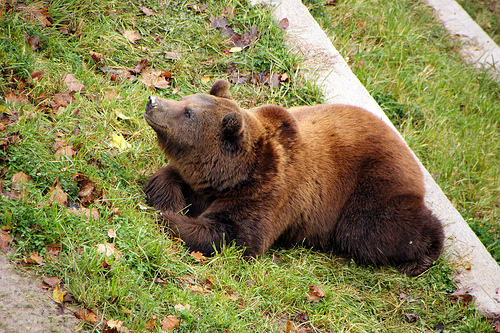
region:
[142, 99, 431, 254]
bear is brown in color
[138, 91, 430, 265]
brown bear is laying on grass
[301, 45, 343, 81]
this is a concrete step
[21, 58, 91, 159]
the grass is green in color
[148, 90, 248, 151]
bear is looking upwards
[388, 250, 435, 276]
this is a bears back paw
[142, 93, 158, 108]
bears nose is black in color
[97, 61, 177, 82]
fallen leaves lying on top of grass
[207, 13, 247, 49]
dead leaves are brown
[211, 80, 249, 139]
brown bear has ears perked up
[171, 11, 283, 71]
leaves in the grass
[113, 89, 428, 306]
bear on the grass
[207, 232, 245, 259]
blades of the grass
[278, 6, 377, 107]
barrier in the grass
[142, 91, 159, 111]
nose of the bear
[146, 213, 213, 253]
paw in the grass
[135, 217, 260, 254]
paw of the bear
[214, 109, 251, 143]
ear of the bear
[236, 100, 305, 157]
scruff of the bears neck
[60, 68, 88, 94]
leaf in the grass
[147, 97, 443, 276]
A brown bear on grass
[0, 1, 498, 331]
Brown leaves spread on grass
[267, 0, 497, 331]
Two white marked areas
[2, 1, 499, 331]
The grass filled space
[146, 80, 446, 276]
The bear with raised ears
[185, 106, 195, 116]
An open bear eye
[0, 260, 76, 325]
The grass free space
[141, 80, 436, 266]
The bear lying on grass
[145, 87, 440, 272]
The bear with a raised head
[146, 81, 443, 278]
A bear with its behind on white surface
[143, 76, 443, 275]
A grizzly bear laying down.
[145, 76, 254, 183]
A grizzly bears head.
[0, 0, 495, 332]
A patch of green grass.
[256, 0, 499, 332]
A set of cement steps.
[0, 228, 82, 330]
An area of dirt.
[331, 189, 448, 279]
A grizzly bears dark brown leg.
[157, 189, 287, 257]
A grizzly bears front leg.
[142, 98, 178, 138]
A brown bear snout.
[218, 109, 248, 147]
An ear of a grizzly bear.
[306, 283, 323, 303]
A dead brown leaf.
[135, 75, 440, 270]
Brown bear lying on green grass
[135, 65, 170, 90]
Brown leaf next to bear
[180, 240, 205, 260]
Brown leaf next to bear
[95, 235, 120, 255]
Brown leaf near brown bear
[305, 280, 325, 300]
Brown leaf near brown bear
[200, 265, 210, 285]
Brown leaf next to bear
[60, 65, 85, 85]
Brown leaf next to bear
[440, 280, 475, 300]
Brown leaf next to bear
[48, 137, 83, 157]
Brown leaf next to bear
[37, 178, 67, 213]
Brown leaf next to bear